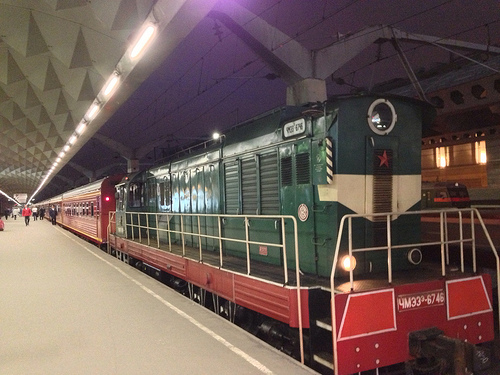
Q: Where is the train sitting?
A: At the station.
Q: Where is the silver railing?
A: On the train.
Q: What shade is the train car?
A: Green.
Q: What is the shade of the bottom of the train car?
A: Red.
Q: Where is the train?
A: In the station.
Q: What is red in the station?
A: The train.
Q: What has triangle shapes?
A: The ceiling.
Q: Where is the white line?
A: On the platform.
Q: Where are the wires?
A: Above the train.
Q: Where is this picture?
A: Train station.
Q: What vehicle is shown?
A: Train.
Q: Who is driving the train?
A: Conductor.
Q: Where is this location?
A: Train stop.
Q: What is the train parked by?
A: Platform.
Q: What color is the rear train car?
A: Green.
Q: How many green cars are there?
A: One.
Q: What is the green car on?
A: Rolling platform.